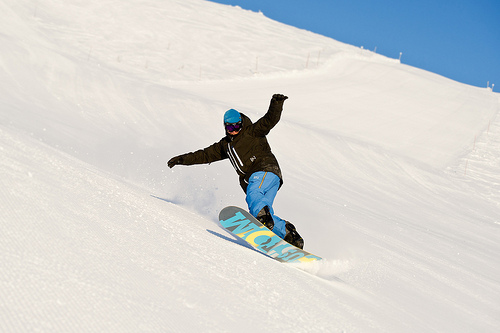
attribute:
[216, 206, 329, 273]
snowboard — black, white, yellow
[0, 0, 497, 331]
snow — fluffy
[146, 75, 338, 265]
person — snow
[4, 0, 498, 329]
slope — snowy, white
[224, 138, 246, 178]
stripes — white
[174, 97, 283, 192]
coat — black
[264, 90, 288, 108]
glove — black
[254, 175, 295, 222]
pants — blue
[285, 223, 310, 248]
boot — black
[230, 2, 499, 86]
sky — blue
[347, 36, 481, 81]
sky — clear, blue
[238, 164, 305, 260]
pants — blue